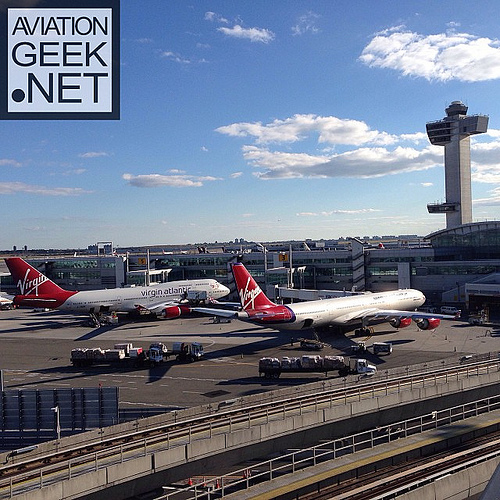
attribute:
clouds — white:
[224, 21, 488, 190]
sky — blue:
[8, 13, 487, 221]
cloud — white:
[216, 105, 435, 186]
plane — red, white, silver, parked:
[183, 257, 467, 345]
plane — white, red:
[3, 247, 234, 337]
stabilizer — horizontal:
[187, 302, 330, 323]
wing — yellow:
[366, 305, 460, 323]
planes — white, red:
[5, 234, 471, 347]